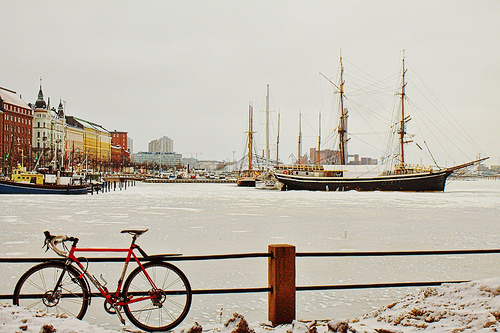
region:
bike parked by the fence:
[30, 222, 230, 332]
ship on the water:
[254, 72, 466, 207]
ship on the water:
[217, 71, 354, 215]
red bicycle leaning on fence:
[14, 226, 200, 331]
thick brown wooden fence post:
[264, 240, 299, 332]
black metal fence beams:
[0, 242, 498, 304]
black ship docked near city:
[269, 43, 491, 198]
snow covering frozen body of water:
[0, 175, 498, 327]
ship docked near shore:
[233, 97, 265, 190]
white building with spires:
[26, 72, 68, 176]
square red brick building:
[0, 83, 36, 185]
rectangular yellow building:
[63, 112, 113, 169]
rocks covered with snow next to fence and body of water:
[0, 272, 498, 332]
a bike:
[5, 228, 215, 322]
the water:
[180, 196, 272, 246]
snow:
[420, 285, 476, 327]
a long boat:
[279, 153, 459, 188]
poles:
[319, 245, 372, 292]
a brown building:
[5, 90, 29, 150]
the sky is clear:
[83, 10, 218, 92]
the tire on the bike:
[165, 270, 195, 308]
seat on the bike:
[116, 225, 151, 240]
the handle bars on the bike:
[40, 227, 75, 249]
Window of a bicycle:
[9, 228, 226, 330]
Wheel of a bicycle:
[10, 252, 95, 331]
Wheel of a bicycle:
[121, 257, 206, 330]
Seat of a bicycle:
[120, 224, 157, 241]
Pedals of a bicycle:
[98, 274, 133, 329]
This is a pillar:
[256, 232, 311, 326]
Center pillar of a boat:
[385, 41, 412, 186]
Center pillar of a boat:
[330, 47, 358, 177]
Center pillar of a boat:
[309, 108, 326, 174]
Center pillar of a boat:
[292, 102, 306, 172]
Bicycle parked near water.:
[14, 226, 196, 331]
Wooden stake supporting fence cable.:
[266, 245, 296, 325]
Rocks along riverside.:
[364, 278, 499, 331]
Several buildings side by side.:
[0, 87, 130, 165]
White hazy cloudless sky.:
[122, 24, 251, 94]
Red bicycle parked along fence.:
[12, 228, 198, 331]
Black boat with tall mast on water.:
[275, 47, 488, 195]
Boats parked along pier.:
[10, 146, 107, 195]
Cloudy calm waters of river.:
[136, 193, 326, 231]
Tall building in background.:
[147, 137, 174, 154]